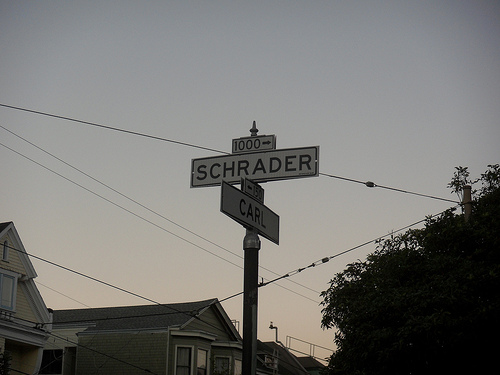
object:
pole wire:
[219, 205, 462, 302]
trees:
[325, 165, 500, 374]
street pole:
[243, 232, 261, 374]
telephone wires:
[216, 204, 464, 304]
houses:
[0, 220, 55, 374]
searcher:
[268, 319, 336, 364]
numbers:
[232, 136, 263, 151]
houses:
[28, 308, 104, 366]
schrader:
[190, 134, 321, 247]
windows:
[182, 346, 194, 362]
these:
[62, 142, 111, 206]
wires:
[0, 240, 247, 341]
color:
[85, 219, 125, 274]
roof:
[52, 296, 241, 342]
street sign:
[196, 154, 314, 181]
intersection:
[36, 307, 79, 374]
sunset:
[258, 250, 323, 326]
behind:
[69, 222, 180, 302]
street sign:
[220, 179, 281, 246]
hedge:
[321, 164, 500, 374]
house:
[45, 293, 244, 373]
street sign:
[190, 134, 320, 187]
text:
[235, 197, 268, 229]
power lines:
[0, 104, 461, 205]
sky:
[2, 0, 500, 367]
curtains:
[177, 344, 190, 365]